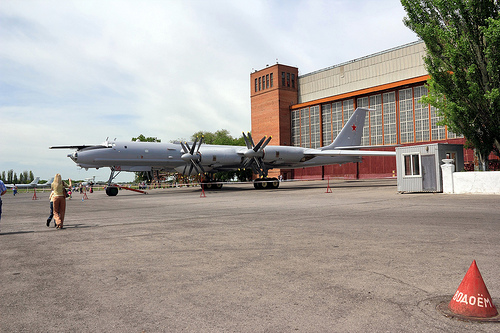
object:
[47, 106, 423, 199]
airplane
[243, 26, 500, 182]
building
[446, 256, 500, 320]
cone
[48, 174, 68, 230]
woman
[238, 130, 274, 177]
propeller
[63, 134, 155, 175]
front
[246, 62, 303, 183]
tower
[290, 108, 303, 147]
window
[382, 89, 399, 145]
window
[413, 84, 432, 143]
window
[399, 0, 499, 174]
tree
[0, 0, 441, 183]
sky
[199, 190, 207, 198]
red triangle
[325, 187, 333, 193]
red triangle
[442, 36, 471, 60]
leaves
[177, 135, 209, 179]
propeller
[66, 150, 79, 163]
propeller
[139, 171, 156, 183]
propeller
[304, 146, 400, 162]
wing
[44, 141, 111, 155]
wing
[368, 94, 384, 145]
wing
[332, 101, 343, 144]
window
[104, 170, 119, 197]
landing gear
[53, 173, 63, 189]
hair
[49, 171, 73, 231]
person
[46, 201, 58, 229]
jeans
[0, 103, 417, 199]
parking lot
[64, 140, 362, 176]
airplane body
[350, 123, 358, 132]
star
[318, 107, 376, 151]
tail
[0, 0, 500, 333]
picture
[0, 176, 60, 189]
airplane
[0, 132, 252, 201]
background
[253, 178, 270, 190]
wheels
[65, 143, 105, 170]
nose